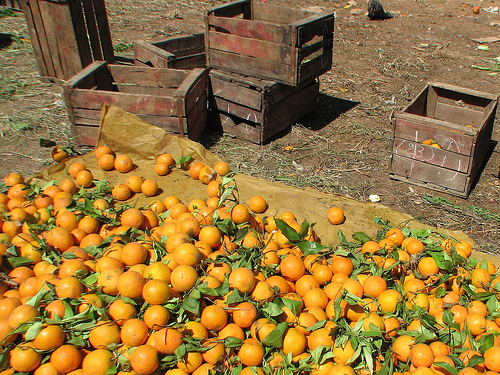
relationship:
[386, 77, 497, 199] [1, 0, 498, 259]
crates laying on dirt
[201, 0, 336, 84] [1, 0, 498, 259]
crates laying on dirt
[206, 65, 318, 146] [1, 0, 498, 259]
crates laying on dirt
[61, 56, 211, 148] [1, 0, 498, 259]
crates laying on dirt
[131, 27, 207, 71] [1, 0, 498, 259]
crates laying on dirt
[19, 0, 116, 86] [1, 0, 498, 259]
crates laying on dirt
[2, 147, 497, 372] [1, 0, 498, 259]
oranges laying on dirt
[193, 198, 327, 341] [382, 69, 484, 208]
oranges laying inside crate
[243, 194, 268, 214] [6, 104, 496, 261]
orange on top of bag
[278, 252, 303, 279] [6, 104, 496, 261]
orange on top of bag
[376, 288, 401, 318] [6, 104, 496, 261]
orange on top of bag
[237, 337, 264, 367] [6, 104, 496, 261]
orange on top of bag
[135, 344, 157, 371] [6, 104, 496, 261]
orange on top of bag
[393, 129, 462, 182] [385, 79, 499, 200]
writing on side of box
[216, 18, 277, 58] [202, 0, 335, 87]
number sign on side of crate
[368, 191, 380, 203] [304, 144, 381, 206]
debri on ground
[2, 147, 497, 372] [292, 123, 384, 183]
oranges on ground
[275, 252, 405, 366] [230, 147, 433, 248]
oranges on ground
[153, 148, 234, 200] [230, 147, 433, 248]
oranges on ground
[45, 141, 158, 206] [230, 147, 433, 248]
oranges on ground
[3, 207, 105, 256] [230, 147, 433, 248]
oranges on ground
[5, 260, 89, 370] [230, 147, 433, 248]
oranges on ground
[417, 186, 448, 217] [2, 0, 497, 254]
grass on ground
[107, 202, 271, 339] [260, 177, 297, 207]
oranges laying brown paper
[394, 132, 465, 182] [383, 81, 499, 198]
writing on side of crate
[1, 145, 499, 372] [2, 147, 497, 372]
leaves on end of oranges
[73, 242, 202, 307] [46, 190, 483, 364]
batch of oranges